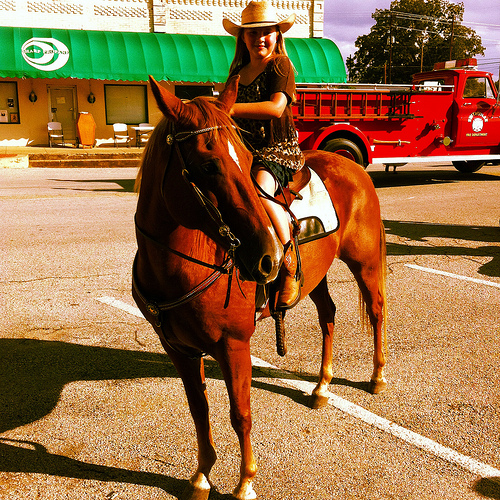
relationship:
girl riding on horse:
[221, 2, 306, 310] [133, 75, 389, 499]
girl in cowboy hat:
[221, 2, 306, 310] [223, 2, 295, 35]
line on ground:
[406, 261, 498, 289] [4, 167, 135, 499]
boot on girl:
[278, 238, 306, 312] [221, 2, 306, 310]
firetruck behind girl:
[295, 59, 498, 161] [221, 2, 306, 310]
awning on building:
[2, 29, 350, 85] [1, 1, 150, 143]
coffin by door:
[75, 113, 100, 147] [50, 84, 78, 145]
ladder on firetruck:
[298, 86, 415, 121] [295, 59, 498, 161]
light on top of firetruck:
[433, 59, 478, 68] [295, 59, 498, 161]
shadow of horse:
[1, 339, 100, 481] [133, 75, 389, 499]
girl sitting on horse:
[221, 2, 306, 310] [133, 75, 389, 499]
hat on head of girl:
[223, 2, 295, 35] [221, 2, 306, 310]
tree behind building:
[346, 1, 485, 84] [1, 1, 150, 143]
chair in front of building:
[47, 122, 64, 145] [1, 1, 150, 143]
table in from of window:
[131, 124, 159, 132] [103, 82, 148, 124]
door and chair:
[50, 84, 78, 145] [112, 123, 129, 145]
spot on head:
[227, 139, 243, 171] [150, 75, 287, 284]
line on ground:
[328, 393, 499, 480] [4, 167, 135, 499]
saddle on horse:
[282, 161, 313, 207] [133, 75, 389, 499]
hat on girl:
[223, 2, 295, 35] [221, 2, 306, 310]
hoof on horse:
[184, 479, 215, 500] [133, 75, 389, 499]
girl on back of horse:
[221, 2, 306, 310] [133, 75, 389, 499]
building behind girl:
[1, 1, 150, 143] [221, 2, 306, 310]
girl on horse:
[221, 2, 306, 310] [133, 75, 389, 499]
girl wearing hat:
[221, 2, 306, 310] [223, 2, 295, 35]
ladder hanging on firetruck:
[298, 86, 415, 121] [295, 59, 498, 161]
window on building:
[2, 80, 21, 123] [1, 1, 150, 143]